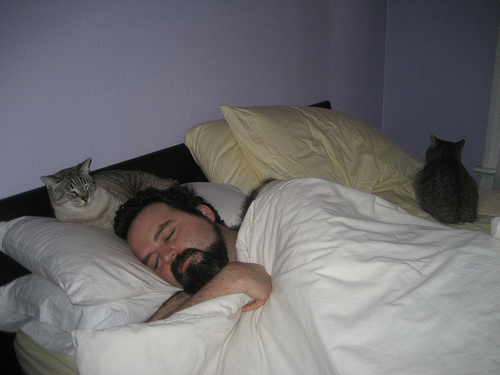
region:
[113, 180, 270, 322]
a man sleeping in a bed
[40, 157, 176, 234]
a cat sleeping above a man's head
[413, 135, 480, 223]
a cat laying on yellow sheets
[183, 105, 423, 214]
yellow pillows on a bed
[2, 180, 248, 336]
white pillows on a bed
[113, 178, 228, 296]
a man with black hair and black beard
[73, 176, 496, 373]
a white bed-cover on a bed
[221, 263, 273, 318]
a man holding a bed-cover with his hand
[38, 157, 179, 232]
a gray cat with a white belly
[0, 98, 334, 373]
a wooden bed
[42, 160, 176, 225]
a white and gray cat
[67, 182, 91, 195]
the closed eyes of the cat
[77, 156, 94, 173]
the cat's ear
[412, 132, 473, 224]
a dark gray cat laying on the bed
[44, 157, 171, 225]
a light gray cat laying on a pillow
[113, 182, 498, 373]
a man asleep under covers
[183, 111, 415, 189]
two yellow pillowcases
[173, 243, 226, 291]
a beard on the man's face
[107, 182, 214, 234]
a head of curly brown hair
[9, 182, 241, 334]
two white pillows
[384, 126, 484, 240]
a cat laying on a bed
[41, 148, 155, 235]
a cat laying on a pillow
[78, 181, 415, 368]
a man asleep in a bed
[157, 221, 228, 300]
a man with facial hair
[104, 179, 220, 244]
a man with black hair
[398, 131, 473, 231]
a black cat laying on a bed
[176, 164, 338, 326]
a man laying under the covers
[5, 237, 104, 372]
two white pillows on a bed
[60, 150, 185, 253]
a cat laying next to a man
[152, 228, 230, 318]
a man with a beard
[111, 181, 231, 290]
the head of a man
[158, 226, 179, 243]
the eye of a man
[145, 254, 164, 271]
the eye of a man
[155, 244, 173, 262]
the nose of a man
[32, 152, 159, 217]
a sleeping cat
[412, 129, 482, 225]
a sleeping cat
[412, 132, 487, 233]
a black cat sleeping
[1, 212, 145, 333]
a group of white pillows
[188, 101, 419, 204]
a group of yellow pillows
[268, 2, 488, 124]
shadows on a wall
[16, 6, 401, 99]
The wall is the color white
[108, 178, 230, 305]
The head of the man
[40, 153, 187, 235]
The cat on the pillow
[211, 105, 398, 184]
The pillows on the bed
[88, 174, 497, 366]
The man is covered in a blanket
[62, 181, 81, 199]
The eye of the cat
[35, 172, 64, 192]
The ear of the cat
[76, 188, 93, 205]
The nose of the cat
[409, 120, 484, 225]
The cat is the color gray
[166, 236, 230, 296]
The man has a beard